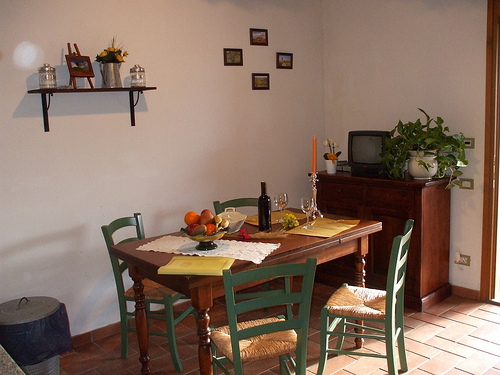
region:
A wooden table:
[110, 205, 380, 373]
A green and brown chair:
[316, 219, 411, 373]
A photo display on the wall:
[223, 26, 294, 91]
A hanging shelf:
[29, 87, 156, 132]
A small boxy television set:
[347, 130, 395, 175]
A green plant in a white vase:
[379, 107, 469, 187]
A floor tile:
[435, 319, 478, 341]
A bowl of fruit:
[180, 207, 230, 249]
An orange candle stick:
[311, 135, 317, 175]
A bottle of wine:
[257, 180, 272, 232]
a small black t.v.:
[344, 132, 387, 171]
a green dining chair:
[320, 218, 422, 373]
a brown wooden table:
[112, 200, 384, 373]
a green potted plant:
[379, 104, 482, 189]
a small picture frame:
[249, 73, 274, 90]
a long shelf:
[31, 81, 159, 95]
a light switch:
[454, 177, 476, 192]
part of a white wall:
[325, 0, 470, 70]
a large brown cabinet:
[317, 167, 454, 310]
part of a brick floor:
[403, 295, 498, 373]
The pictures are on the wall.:
[209, 13, 305, 96]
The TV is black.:
[345, 124, 387, 177]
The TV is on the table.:
[335, 123, 456, 305]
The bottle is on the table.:
[246, 181, 278, 233]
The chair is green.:
[220, 259, 317, 354]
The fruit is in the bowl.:
[173, 200, 228, 255]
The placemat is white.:
[132, 219, 269, 280]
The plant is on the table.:
[377, 112, 473, 197]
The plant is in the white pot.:
[386, 112, 471, 194]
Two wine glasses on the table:
[272, 189, 315, 240]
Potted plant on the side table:
[383, 117, 467, 182]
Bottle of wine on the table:
[255, 178, 274, 234]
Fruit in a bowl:
[180, 206, 227, 251]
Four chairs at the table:
[102, 193, 411, 371]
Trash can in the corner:
[2, 291, 76, 373]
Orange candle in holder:
[307, 130, 321, 219]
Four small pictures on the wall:
[221, 23, 293, 93]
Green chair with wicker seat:
[314, 218, 417, 373]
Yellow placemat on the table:
[285, 209, 359, 239]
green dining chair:
[220, 266, 320, 371]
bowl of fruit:
[180, 205, 230, 250]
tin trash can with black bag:
[0, 295, 72, 370]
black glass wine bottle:
[256, 180, 268, 226]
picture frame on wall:
[245, 21, 271, 46]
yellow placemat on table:
[160, 251, 220, 271]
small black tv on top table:
[345, 125, 386, 175]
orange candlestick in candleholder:
[305, 135, 316, 165]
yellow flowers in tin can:
[92, 45, 122, 85]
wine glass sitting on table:
[296, 197, 316, 227]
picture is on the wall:
[224, 48, 244, 67]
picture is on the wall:
[250, 72, 268, 89]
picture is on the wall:
[277, 52, 294, 69]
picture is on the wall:
[250, 27, 270, 43]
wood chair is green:
[211, 256, 313, 373]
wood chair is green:
[321, 219, 416, 371]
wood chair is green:
[214, 196, 274, 213]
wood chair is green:
[102, 211, 209, 373]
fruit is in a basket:
[186, 213, 200, 227]